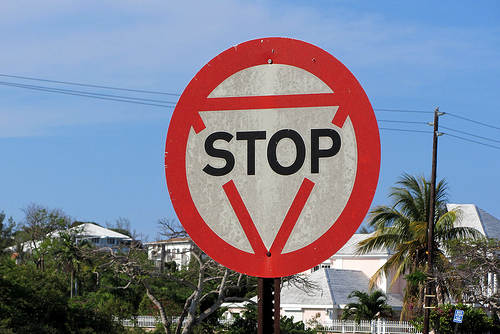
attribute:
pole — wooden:
[418, 107, 444, 332]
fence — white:
[308, 317, 421, 332]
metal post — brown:
[235, 260, 307, 329]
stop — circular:
[162, 35, 382, 280]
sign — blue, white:
[451, 307, 466, 324]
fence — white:
[312, 315, 422, 332]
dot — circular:
[269, 289, 275, 294]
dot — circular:
[269, 299, 275, 303]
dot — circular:
[270, 307, 275, 311]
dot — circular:
[269, 316, 275, 320]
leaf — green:
[396, 177, 438, 210]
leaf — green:
[368, 206, 415, 231]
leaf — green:
[358, 220, 413, 253]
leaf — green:
[434, 226, 481, 249]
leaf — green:
[433, 175, 448, 226]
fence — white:
[269, 294, 466, 331]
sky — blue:
[20, 40, 121, 76]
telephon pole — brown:
[418, 105, 453, 332]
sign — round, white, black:
[164, 36, 379, 279]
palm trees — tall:
[370, 172, 472, 330]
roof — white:
[81, 221, 106, 236]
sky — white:
[348, 17, 468, 84]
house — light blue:
[23, 218, 130, 287]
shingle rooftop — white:
[252, 268, 398, 306]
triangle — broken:
[182, 87, 360, 256]